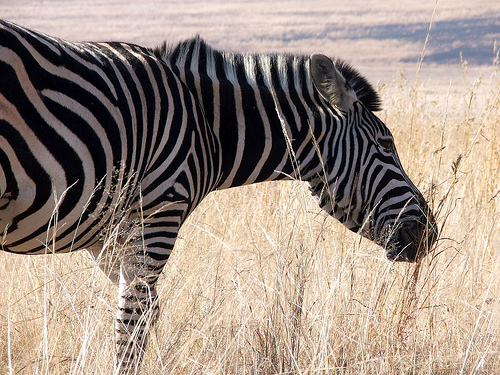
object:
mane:
[153, 32, 385, 113]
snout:
[388, 215, 437, 260]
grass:
[0, 0, 500, 374]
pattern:
[0, 28, 121, 253]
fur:
[130, 107, 156, 131]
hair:
[331, 56, 381, 108]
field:
[0, 0, 499, 374]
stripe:
[228, 56, 265, 187]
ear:
[311, 53, 347, 106]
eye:
[376, 136, 395, 150]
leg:
[116, 203, 186, 373]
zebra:
[0, 21, 435, 372]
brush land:
[0, 0, 500, 373]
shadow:
[245, 12, 499, 69]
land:
[0, 0, 498, 374]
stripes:
[0, 118, 53, 236]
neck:
[199, 73, 321, 191]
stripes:
[128, 229, 178, 240]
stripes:
[0, 148, 20, 211]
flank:
[0, 21, 446, 374]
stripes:
[368, 169, 403, 212]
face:
[338, 112, 438, 264]